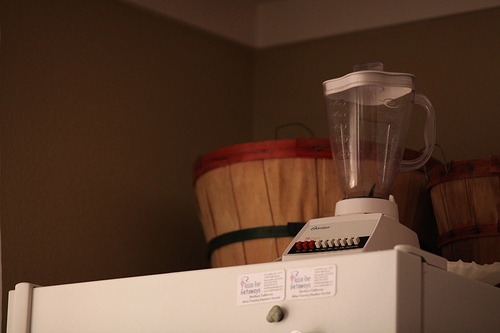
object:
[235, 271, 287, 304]
there is a note.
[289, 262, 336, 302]
there is a note.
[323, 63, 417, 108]
there is a lid.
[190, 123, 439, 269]
there is a basket.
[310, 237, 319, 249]
there are buttons.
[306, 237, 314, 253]
buttons are red.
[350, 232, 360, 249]
buttons are white.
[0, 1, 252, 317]
there is a wall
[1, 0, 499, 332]
wall is tan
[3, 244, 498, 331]
fridge is white.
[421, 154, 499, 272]
there are baskets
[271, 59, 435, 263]
blender is empty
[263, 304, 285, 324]
there is a magnet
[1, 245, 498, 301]
fridge has top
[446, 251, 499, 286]
there are filters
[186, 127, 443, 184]
basket top is red.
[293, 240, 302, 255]
buttons  on blender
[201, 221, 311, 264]
there is green